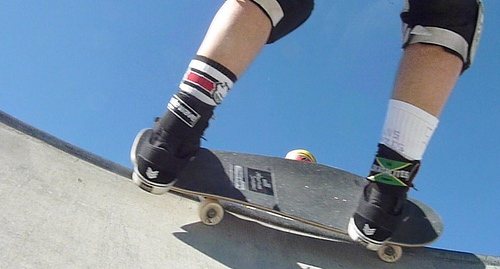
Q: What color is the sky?
A: Blue.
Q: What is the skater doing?
A: Skating.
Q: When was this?
A: Daytime.